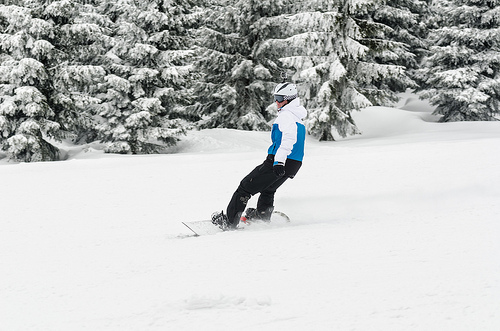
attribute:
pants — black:
[224, 152, 301, 226]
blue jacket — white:
[254, 95, 316, 163]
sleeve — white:
[273, 110, 299, 164]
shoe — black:
[210, 212, 235, 229]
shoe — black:
[247, 205, 272, 222]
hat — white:
[269, 78, 300, 105]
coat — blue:
[266, 122, 305, 162]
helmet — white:
[274, 83, 298, 101]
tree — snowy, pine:
[236, 0, 377, 143]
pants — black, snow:
[227, 160, 290, 224]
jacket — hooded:
[256, 99, 312, 166]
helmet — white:
[267, 75, 303, 99]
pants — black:
[213, 155, 288, 224]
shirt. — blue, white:
[247, 61, 334, 173]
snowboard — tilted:
[185, 206, 292, 239]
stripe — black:
[275, 81, 293, 95]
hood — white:
[286, 98, 310, 122]